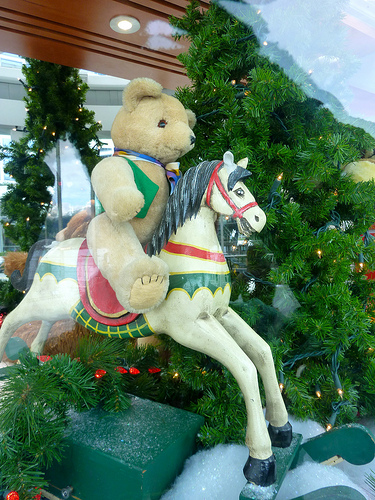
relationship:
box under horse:
[51, 384, 188, 496] [10, 150, 292, 482]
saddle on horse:
[58, 214, 165, 344] [1, 141, 300, 495]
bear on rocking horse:
[79, 72, 202, 319] [0, 150, 293, 488]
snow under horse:
[162, 406, 362, 498] [10, 150, 292, 482]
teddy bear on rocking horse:
[86, 77, 196, 313] [0, 150, 293, 488]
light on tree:
[92, 367, 105, 376] [20, 63, 372, 500]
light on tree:
[112, 359, 128, 375] [9, 146, 374, 500]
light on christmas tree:
[277, 172, 284, 181] [157, 0, 373, 428]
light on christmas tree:
[315, 245, 323, 257] [157, 0, 373, 428]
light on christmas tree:
[358, 262, 363, 268] [157, 0, 373, 428]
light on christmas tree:
[245, 88, 252, 94] [157, 0, 373, 428]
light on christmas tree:
[278, 369, 287, 390] [68, 1, 373, 452]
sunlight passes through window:
[86, 77, 109, 124] [8, 95, 167, 283]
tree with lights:
[229, 82, 366, 340] [280, 130, 363, 340]